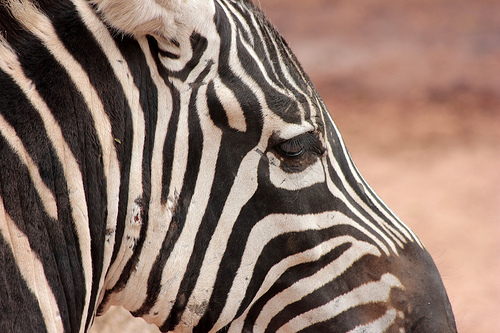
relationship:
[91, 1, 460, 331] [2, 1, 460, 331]
head belonging to zebra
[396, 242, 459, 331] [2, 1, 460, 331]
nose belonging to zebra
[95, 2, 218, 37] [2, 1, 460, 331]
ear of zebra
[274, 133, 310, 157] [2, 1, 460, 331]
eye on zebra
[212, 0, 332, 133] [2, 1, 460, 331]
forehead belonging to zebra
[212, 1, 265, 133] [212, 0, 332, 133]
stripe adorning forehead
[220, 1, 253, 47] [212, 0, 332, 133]
stripe adorning forehead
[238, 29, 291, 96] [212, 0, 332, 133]
stripe adorning forehead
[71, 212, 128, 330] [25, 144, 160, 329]
wrinkles in neck area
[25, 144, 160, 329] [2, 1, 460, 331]
neck area of zebra